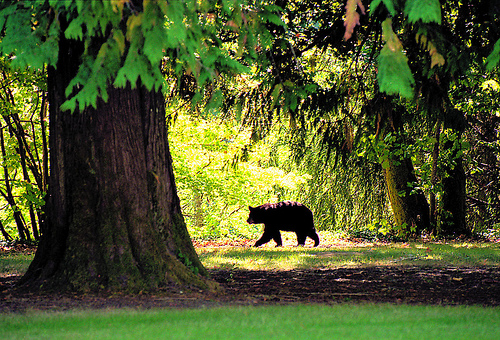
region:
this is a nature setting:
[24, 27, 448, 296]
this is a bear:
[215, 156, 419, 314]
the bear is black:
[255, 187, 344, 254]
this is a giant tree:
[55, 118, 193, 233]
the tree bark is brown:
[31, 142, 153, 246]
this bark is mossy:
[55, 196, 186, 303]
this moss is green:
[51, 237, 167, 304]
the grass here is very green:
[165, 315, 350, 326]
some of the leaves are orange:
[301, 13, 377, 43]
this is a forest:
[193, 58, 496, 317]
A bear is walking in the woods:
[27, 12, 462, 328]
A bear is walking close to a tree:
[11, 45, 483, 312]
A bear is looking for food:
[30, 35, 455, 305]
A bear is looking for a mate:
[40, 32, 496, 322]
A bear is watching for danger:
[40, 40, 480, 305]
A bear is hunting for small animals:
[5, 30, 487, 330]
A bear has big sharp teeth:
[30, 71, 476, 336]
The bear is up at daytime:
[16, 50, 481, 318]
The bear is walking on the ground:
[37, 75, 447, 305]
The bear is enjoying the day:
[45, 94, 460, 304]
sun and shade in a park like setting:
[2, 5, 493, 335]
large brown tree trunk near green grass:
[15, 0, 215, 297]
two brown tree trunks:
[375, 123, 472, 243]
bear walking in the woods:
[245, 197, 327, 249]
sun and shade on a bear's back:
[253, 200, 310, 211]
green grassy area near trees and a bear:
[2, 298, 495, 338]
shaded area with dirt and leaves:
[216, 261, 487, 306]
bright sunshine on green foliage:
[177, 135, 319, 197]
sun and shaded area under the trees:
[188, 242, 432, 276]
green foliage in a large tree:
[0, 11, 248, 109]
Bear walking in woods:
[246, 200, 320, 248]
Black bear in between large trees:
[245, 202, 320, 248]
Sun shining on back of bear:
[261, 201, 306, 210]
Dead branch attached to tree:
[341, 2, 363, 40]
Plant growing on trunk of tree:
[153, 202, 202, 277]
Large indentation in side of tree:
[19, 107, 117, 294]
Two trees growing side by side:
[383, 67, 470, 242]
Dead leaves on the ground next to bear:
[192, 236, 249, 247]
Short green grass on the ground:
[196, 249, 499, 264]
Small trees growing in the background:
[171, 119, 314, 240]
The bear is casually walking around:
[11, 15, 491, 338]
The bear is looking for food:
[25, 10, 467, 320]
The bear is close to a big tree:
[35, 46, 471, 311]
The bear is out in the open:
[28, 35, 463, 313]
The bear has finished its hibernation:
[5, 32, 480, 333]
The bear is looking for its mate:
[25, 27, 490, 320]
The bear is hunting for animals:
[1, 32, 497, 327]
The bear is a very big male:
[0, 50, 495, 327]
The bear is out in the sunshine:
[21, 46, 477, 331]